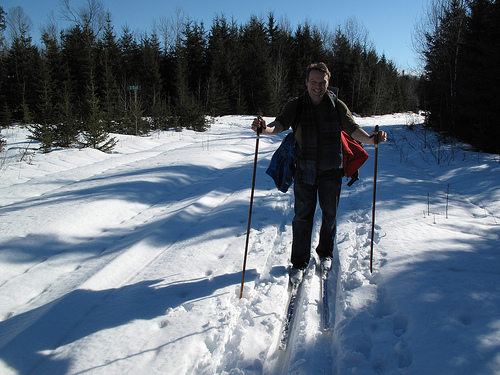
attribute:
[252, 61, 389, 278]
man — skiing, smiling, grinning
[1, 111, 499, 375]
snow — fluffy, white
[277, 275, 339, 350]
skis — snow skis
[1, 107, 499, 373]
ground — snowy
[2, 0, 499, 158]
trees — green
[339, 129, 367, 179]
backpack — red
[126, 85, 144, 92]
sign — green, white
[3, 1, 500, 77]
sky — clear, blue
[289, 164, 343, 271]
jeans — blue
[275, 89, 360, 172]
jacket — blue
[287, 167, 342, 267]
pants — black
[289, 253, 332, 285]
boots — white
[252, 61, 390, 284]
skier — smiling